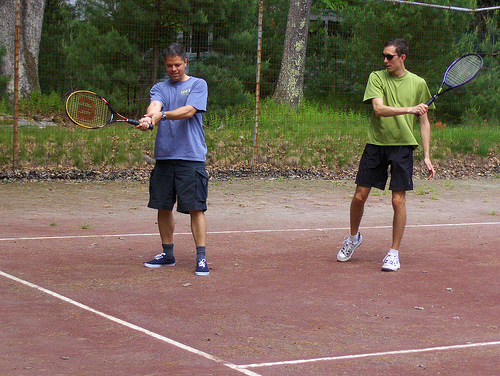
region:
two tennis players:
[51, 17, 484, 287]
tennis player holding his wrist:
[133, 87, 233, 153]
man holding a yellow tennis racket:
[59, 68, 162, 150]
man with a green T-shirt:
[343, 67, 444, 139]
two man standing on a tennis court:
[57, 10, 492, 312]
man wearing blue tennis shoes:
[127, 240, 223, 284]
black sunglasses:
[376, 51, 405, 65]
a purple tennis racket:
[416, 42, 491, 121]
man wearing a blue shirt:
[148, 77, 218, 150]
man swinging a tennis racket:
[347, 33, 494, 156]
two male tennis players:
[64, 37, 483, 274]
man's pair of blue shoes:
[143, 255, 210, 274]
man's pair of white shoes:
[336, 233, 401, 270]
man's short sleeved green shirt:
[363, 67, 434, 147]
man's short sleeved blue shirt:
[148, 77, 209, 161]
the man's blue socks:
[160, 242, 205, 258]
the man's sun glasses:
[379, 51, 404, 58]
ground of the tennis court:
[157, 277, 408, 328]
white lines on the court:
[183, 340, 342, 374]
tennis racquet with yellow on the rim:
[65, 87, 154, 132]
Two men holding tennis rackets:
[47, 17, 481, 299]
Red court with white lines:
[25, 198, 429, 372]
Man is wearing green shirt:
[362, 30, 436, 177]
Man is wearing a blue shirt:
[141, 43, 218, 157]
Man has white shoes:
[322, 218, 422, 289]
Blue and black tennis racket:
[397, 42, 484, 117]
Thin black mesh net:
[10, 5, 485, 176]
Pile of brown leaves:
[17, 147, 475, 184]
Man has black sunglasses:
[376, 30, 426, 91]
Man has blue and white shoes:
[133, 235, 207, 292]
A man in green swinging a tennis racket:
[330, 22, 490, 299]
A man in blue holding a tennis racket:
[39, 31, 290, 301]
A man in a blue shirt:
[122, 27, 224, 288]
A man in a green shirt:
[327, 28, 459, 293]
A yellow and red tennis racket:
[44, 73, 159, 145]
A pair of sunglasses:
[374, 48, 407, 63]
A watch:
[158, 107, 169, 122]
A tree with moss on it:
[270, 3, 333, 123]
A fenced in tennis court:
[5, 2, 485, 372]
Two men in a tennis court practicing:
[5, 12, 496, 369]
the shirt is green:
[357, 31, 449, 202]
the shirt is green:
[359, 77, 451, 152]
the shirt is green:
[371, 76, 492, 236]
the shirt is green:
[370, 75, 411, 130]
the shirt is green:
[320, 106, 486, 173]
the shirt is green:
[363, 75, 433, 110]